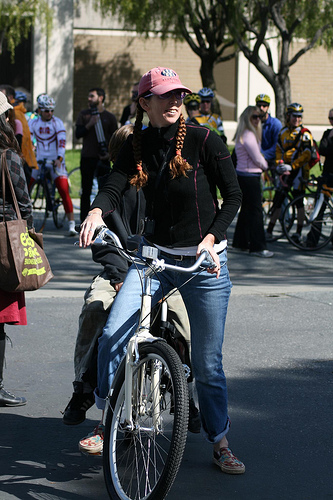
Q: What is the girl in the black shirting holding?
A: A bike.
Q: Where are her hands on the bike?
A: Handlebars.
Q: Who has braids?
A: Girl in front.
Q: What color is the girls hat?
A: Pink.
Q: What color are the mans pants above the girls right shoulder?
A: Red.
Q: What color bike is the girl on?
A: White.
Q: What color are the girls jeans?
A: Blue.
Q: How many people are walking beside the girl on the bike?
A: 1.